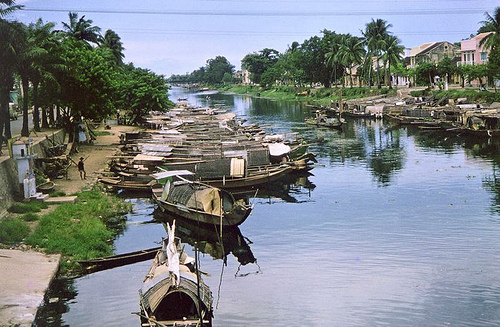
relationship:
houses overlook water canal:
[334, 35, 499, 84] [55, 73, 494, 325]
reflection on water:
[480, 157, 498, 222] [120, 69, 480, 325]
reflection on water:
[364, 129, 404, 189] [120, 69, 480, 325]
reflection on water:
[247, 101, 367, 164] [120, 69, 480, 325]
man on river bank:
[76, 156, 87, 181] [15, 112, 148, 324]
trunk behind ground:
[15, 92, 30, 144] [0, 71, 500, 180]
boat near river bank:
[98, 163, 315, 189] [0, 112, 148, 327]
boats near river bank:
[144, 162, 254, 222] [0, 112, 148, 327]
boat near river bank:
[130, 220, 212, 327] [0, 112, 148, 327]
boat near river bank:
[128, 132, 292, 153] [0, 112, 148, 327]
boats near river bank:
[143, 107, 236, 132] [0, 112, 148, 327]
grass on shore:
[39, 205, 122, 262] [9, 245, 64, 302]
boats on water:
[131, 92, 496, 189] [58, 77, 497, 325]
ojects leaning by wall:
[0, 125, 47, 208] [5, 119, 69, 226]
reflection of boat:
[222, 227, 264, 281] [144, 163, 259, 226]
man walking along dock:
[73, 156, 87, 178] [79, 123, 116, 215]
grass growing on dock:
[39, 181, 137, 267] [0, 194, 70, 317]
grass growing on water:
[39, 181, 137, 267] [312, 135, 494, 325]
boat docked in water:
[236, 163, 280, 187] [318, 147, 388, 254]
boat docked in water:
[151, 154, 197, 176] [318, 147, 388, 254]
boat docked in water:
[111, 141, 308, 163] [318, 147, 388, 254]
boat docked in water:
[196, 132, 238, 147] [318, 147, 388, 254]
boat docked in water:
[155, 133, 206, 153] [318, 147, 388, 254]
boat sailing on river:
[314, 108, 347, 130] [63, 75, 496, 322]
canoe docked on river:
[72, 238, 161, 271] [63, 75, 496, 322]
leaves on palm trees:
[309, 38, 340, 87] [325, 16, 402, 88]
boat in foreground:
[130, 220, 212, 323] [151, 52, 427, 142]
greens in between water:
[35, 181, 130, 264] [133, 83, 495, 324]